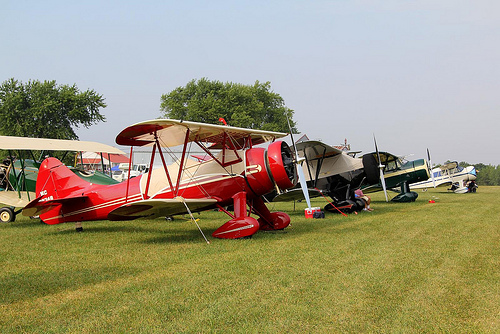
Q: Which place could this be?
A: It is a field.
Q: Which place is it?
A: It is a field.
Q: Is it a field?
A: Yes, it is a field.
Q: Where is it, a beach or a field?
A: It is a field.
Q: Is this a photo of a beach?
A: No, the picture is showing a field.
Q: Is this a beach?
A: No, it is a field.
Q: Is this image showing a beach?
A: No, the picture is showing a field.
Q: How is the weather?
A: It is clear.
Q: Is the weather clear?
A: Yes, it is clear.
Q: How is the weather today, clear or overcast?
A: It is clear.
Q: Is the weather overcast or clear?
A: It is clear.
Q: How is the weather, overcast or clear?
A: It is clear.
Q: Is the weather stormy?
A: No, it is clear.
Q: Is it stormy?
A: No, it is clear.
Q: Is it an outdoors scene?
A: Yes, it is outdoors.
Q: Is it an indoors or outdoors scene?
A: It is outdoors.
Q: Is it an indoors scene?
A: No, it is outdoors.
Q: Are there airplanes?
A: Yes, there are airplanes.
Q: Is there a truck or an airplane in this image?
A: Yes, there are airplanes.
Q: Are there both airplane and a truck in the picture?
A: No, there are airplanes but no trucks.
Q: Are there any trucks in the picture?
A: No, there are no trucks.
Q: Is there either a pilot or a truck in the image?
A: No, there are no trucks or pilots.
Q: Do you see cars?
A: No, there are no cars.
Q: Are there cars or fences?
A: No, there are no cars or fences.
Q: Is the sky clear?
A: Yes, the sky is clear.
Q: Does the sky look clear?
A: Yes, the sky is clear.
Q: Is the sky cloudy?
A: No, the sky is clear.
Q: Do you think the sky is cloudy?
A: No, the sky is clear.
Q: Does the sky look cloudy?
A: No, the sky is clear.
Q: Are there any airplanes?
A: Yes, there is an airplane.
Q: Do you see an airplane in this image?
A: Yes, there is an airplane.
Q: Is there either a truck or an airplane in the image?
A: Yes, there is an airplane.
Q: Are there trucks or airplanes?
A: Yes, there is an airplane.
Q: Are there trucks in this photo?
A: No, there are no trucks.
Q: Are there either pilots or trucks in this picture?
A: No, there are no trucks or pilots.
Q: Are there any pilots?
A: No, there are no pilots.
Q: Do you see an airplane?
A: Yes, there is an airplane.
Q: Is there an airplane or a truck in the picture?
A: Yes, there is an airplane.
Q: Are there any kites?
A: No, there are no kites.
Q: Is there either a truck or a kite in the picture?
A: No, there are no kites or trucks.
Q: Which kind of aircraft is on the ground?
A: The aircraft is an airplane.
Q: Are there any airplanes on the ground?
A: Yes, there is an airplane on the ground.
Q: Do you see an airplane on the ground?
A: Yes, there is an airplane on the ground.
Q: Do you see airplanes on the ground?
A: Yes, there is an airplane on the ground.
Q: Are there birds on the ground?
A: No, there is an airplane on the ground.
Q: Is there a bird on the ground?
A: No, there is an airplane on the ground.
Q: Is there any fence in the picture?
A: No, there are no fences.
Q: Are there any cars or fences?
A: No, there are no fences or cars.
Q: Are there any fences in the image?
A: No, there are no fences.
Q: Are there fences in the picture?
A: No, there are no fences.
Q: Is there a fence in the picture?
A: No, there are no fences.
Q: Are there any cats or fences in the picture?
A: No, there are no fences or cats.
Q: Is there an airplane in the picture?
A: Yes, there is an airplane.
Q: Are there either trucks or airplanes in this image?
A: Yes, there is an airplane.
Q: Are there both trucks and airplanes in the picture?
A: No, there is an airplane but no trucks.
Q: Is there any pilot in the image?
A: No, there are no pilots.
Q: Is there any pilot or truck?
A: No, there are no pilots or trucks.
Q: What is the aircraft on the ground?
A: The aircraft is an airplane.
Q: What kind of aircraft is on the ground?
A: The aircraft is an airplane.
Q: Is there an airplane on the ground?
A: Yes, there is an airplane on the ground.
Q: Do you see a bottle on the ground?
A: No, there is an airplane on the ground.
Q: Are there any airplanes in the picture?
A: Yes, there is an airplane.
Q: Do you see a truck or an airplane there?
A: Yes, there is an airplane.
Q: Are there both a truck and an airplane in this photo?
A: No, there is an airplane but no trucks.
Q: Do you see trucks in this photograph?
A: No, there are no trucks.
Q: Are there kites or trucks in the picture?
A: No, there are no trucks or kites.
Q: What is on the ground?
A: The airplane is on the ground.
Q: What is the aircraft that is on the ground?
A: The aircraft is an airplane.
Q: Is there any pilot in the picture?
A: No, there are no pilots.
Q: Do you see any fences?
A: No, there are no fences.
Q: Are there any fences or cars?
A: No, there are no fences or cars.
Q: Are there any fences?
A: No, there are no fences.